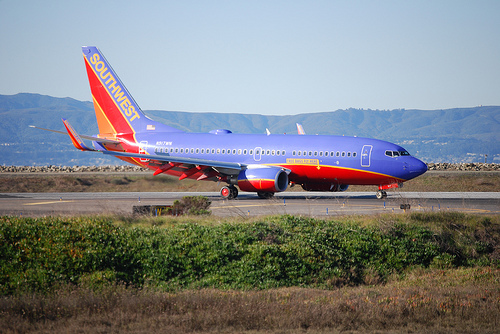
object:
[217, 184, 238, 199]
wheel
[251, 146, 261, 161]
door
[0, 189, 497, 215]
ground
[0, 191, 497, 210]
landing strip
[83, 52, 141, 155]
stripes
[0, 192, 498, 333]
ground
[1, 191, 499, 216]
runway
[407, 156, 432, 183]
nose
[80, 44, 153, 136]
tail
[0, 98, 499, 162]
mountain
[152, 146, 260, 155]
row of windows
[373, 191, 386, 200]
wheel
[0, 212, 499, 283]
green bushes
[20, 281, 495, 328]
dead grass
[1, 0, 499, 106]
sky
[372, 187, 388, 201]
plane wheels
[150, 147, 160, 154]
plane window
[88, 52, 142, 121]
airplane name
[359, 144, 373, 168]
airplane door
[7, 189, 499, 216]
airplane runway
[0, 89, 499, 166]
hills behind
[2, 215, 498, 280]
front bushes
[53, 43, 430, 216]
airplane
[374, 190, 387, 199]
black wheels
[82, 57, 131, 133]
red paint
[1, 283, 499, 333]
dried grass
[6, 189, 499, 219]
black road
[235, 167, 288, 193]
airplane engine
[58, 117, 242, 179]
plane wing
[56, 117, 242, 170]
wing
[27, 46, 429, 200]
an airplane